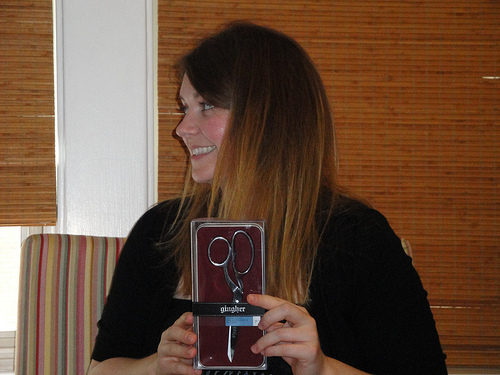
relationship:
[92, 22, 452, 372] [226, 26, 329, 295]
woman has hair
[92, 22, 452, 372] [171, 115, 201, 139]
woman has nose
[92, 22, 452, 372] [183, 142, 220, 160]
woman has mouth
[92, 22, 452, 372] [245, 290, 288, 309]
woman has finger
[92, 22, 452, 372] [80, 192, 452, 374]
woman wearing shirt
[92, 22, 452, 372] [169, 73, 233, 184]
woman has face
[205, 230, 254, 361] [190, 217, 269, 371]
scissors in box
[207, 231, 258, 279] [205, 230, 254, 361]
handle on scissors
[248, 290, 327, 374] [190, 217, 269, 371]
hand on box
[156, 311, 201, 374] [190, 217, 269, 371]
hand holding box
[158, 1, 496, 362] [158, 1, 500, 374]
shade over shade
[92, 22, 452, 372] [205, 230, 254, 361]
woman holding scissors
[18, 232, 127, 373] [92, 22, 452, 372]
chair behind woman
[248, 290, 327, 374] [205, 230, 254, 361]
hand holding scissors